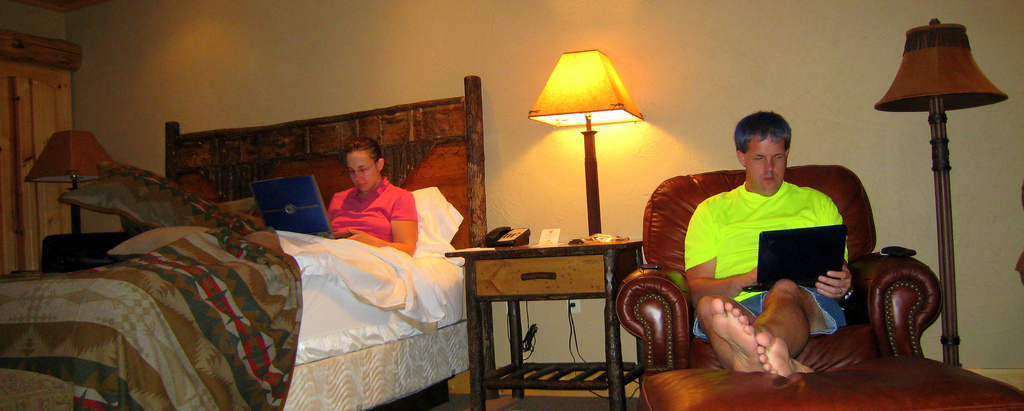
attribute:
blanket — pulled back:
[129, 223, 417, 357]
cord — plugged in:
[513, 297, 619, 362]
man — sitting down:
[697, 130, 868, 329]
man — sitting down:
[286, 134, 455, 256]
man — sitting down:
[675, 95, 864, 381]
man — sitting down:
[613, 80, 909, 403]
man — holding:
[664, 100, 926, 401]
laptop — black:
[695, 201, 836, 297]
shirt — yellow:
[684, 184, 890, 312]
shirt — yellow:
[684, 180, 829, 362]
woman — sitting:
[280, 122, 428, 278]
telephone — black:
[481, 224, 534, 253]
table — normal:
[442, 236, 643, 409]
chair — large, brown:
[613, 163, 1022, 408]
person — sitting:
[682, 111, 857, 379]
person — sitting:
[321, 135, 421, 254]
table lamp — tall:
[523, 44, 642, 245]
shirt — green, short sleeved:
[678, 180, 853, 299]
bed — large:
[4, 72, 499, 407]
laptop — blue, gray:
[249, 171, 351, 241]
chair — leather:
[609, 156, 945, 370]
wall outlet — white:
[564, 292, 582, 316]